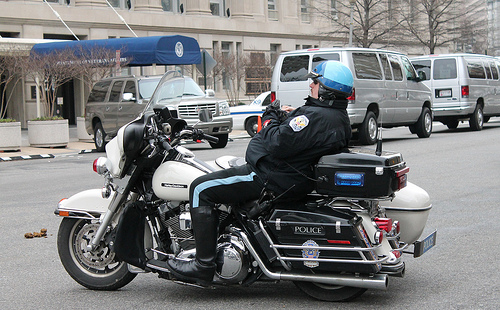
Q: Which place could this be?
A: It is a road.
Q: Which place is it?
A: It is a road.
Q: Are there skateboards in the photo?
A: No, there are no skateboards.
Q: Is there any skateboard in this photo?
A: No, there are no skateboards.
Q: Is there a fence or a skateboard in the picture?
A: No, there are no skateboards or fences.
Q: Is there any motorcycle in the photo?
A: Yes, there is a motorcycle.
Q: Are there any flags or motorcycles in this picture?
A: Yes, there is a motorcycle.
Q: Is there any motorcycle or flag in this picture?
A: Yes, there is a motorcycle.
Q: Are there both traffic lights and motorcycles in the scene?
A: No, there is a motorcycle but no traffic lights.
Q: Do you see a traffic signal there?
A: No, there are no traffic lights.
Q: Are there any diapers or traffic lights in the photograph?
A: No, there are no traffic lights or diapers.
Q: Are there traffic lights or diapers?
A: No, there are no traffic lights or diapers.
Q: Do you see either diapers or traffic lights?
A: No, there are no traffic lights or diapers.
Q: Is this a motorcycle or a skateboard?
A: This is a motorcycle.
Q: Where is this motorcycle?
A: The motorcycle is on the road.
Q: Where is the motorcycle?
A: The motorcycle is on the road.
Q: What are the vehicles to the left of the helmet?
A: The vehicles are cars.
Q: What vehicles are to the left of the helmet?
A: The vehicles are cars.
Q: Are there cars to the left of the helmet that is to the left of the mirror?
A: Yes, there are cars to the left of the helmet.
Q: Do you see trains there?
A: No, there are no trains.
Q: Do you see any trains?
A: No, there are no trains.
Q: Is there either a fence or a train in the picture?
A: No, there are no trains or fences.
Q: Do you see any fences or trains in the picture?
A: No, there are no trains or fences.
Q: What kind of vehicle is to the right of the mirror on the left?
A: The vehicles are cars.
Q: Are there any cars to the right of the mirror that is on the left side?
A: Yes, there are cars to the right of the mirror.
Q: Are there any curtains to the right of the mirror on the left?
A: No, there are cars to the right of the mirror.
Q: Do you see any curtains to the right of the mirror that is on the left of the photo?
A: No, there are cars to the right of the mirror.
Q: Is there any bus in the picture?
A: No, there are no buses.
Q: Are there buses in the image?
A: No, there are no buses.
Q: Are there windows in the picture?
A: Yes, there is a window.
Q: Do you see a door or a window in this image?
A: Yes, there is a window.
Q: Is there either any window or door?
A: Yes, there is a window.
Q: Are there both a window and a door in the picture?
A: Yes, there are both a window and a door.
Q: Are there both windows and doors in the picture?
A: Yes, there are both a window and a door.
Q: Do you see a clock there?
A: No, there are no clocks.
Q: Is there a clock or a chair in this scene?
A: No, there are no clocks or chairs.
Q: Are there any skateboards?
A: No, there are no skateboards.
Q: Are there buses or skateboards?
A: No, there are no skateboards or buses.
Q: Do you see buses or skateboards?
A: No, there are no skateboards or buses.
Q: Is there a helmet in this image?
A: Yes, there is a helmet.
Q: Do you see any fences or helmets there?
A: Yes, there is a helmet.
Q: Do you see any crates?
A: No, there are no crates.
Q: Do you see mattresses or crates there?
A: No, there are no crates or mattresses.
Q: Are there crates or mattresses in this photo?
A: No, there are no crates or mattresses.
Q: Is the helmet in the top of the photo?
A: Yes, the helmet is in the top of the image.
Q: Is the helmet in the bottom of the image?
A: No, the helmet is in the top of the image.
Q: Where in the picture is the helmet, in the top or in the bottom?
A: The helmet is in the top of the image.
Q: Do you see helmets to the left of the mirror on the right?
A: Yes, there is a helmet to the left of the mirror.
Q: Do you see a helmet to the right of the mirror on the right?
A: No, the helmet is to the left of the mirror.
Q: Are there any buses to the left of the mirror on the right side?
A: No, there is a helmet to the left of the mirror.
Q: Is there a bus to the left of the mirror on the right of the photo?
A: No, there is a helmet to the left of the mirror.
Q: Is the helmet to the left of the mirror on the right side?
A: Yes, the helmet is to the left of the mirror.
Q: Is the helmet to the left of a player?
A: No, the helmet is to the left of the mirror.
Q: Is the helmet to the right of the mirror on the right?
A: No, the helmet is to the left of the mirror.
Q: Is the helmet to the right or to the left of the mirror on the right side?
A: The helmet is to the left of the mirror.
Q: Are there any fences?
A: No, there are no fences.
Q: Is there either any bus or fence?
A: No, there are no fences or buses.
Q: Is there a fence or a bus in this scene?
A: No, there are no fences or buses.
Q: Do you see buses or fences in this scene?
A: No, there are no fences or buses.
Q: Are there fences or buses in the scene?
A: No, there are no fences or buses.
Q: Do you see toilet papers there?
A: No, there are no toilet papers.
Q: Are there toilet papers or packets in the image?
A: No, there are no toilet papers or packets.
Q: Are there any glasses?
A: No, there are no glasses.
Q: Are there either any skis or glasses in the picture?
A: No, there are no glasses or skis.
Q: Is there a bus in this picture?
A: No, there are no buses.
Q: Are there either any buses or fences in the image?
A: No, there are no buses or fences.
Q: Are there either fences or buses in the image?
A: No, there are no buses or fences.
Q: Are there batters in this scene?
A: No, there are no batters.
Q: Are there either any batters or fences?
A: No, there are no batters or fences.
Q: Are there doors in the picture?
A: Yes, there is a door.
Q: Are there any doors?
A: Yes, there is a door.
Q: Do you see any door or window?
A: Yes, there is a door.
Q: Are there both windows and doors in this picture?
A: Yes, there are both a door and a window.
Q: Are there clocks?
A: No, there are no clocks.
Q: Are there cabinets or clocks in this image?
A: No, there are no clocks or cabinets.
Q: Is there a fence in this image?
A: No, there are no fences.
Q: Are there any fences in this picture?
A: No, there are no fences.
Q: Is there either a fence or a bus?
A: No, there are no fences or buses.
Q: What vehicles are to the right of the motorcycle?
A: The vehicles are cars.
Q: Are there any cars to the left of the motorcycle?
A: No, the cars are to the right of the motorcycle.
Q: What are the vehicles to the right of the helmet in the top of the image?
A: The vehicles are cars.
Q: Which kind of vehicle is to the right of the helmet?
A: The vehicles are cars.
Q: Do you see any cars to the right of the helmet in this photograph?
A: Yes, there are cars to the right of the helmet.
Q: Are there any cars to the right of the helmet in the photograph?
A: Yes, there are cars to the right of the helmet.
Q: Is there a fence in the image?
A: No, there are no fences.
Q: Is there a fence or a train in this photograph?
A: No, there are no fences or trains.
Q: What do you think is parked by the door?
A: The cars are parked by the door.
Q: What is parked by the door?
A: The cars are parked by the door.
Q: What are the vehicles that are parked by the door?
A: The vehicles are cars.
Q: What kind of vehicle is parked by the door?
A: The vehicles are cars.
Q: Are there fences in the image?
A: No, there are no fences.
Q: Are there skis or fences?
A: No, there are no fences or skis.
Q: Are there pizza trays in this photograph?
A: No, there are no pizza trays.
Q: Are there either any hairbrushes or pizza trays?
A: No, there are no pizza trays or hairbrushes.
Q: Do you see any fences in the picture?
A: No, there are no fences.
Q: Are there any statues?
A: No, there are no statues.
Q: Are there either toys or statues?
A: No, there are no statues or toys.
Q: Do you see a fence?
A: No, there are no fences.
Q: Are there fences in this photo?
A: No, there are no fences.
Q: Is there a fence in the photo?
A: No, there are no fences.